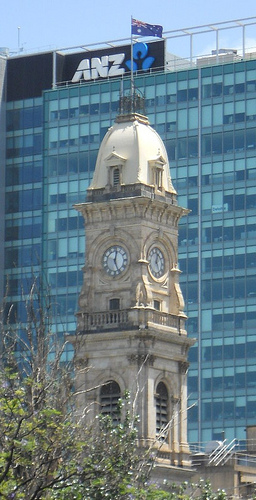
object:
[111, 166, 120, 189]
ventilation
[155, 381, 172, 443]
shutters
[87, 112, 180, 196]
dome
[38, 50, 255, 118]
roof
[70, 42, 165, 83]
advertisemetn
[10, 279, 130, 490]
branches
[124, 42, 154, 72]
blue sign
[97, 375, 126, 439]
blinds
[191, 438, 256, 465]
fence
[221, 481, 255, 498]
fence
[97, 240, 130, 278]
sheep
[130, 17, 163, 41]
flag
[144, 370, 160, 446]
light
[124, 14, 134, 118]
train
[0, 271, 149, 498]
tree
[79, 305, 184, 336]
balcony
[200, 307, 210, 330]
window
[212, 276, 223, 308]
window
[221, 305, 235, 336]
window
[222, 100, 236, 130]
window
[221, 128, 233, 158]
window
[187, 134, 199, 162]
window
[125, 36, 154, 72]
blue man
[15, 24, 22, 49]
flag pole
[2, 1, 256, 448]
scraper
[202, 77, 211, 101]
window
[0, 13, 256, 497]
building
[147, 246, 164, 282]
clock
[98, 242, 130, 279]
clock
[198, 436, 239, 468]
stairs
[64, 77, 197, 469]
clock tower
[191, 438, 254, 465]
balcony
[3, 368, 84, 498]
leaves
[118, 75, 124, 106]
antenna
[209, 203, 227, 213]
advertisement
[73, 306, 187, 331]
railing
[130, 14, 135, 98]
pole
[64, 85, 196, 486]
building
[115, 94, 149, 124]
roof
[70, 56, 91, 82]
letter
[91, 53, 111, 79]
letter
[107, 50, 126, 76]
letter